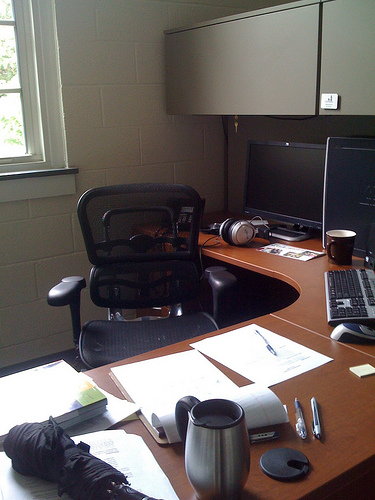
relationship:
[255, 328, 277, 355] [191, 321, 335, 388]
pen on paper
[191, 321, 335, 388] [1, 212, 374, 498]
paper on desk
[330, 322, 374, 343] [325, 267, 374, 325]
mouse next to keyboard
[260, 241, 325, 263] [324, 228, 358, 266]
brochure by mug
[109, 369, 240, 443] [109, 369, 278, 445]
clipboard on clipboard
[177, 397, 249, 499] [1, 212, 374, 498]
mug on desk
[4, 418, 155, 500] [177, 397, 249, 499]
umbrella beside mug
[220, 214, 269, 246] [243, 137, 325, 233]
headphones in front of computer monitor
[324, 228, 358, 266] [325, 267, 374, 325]
mug by keyboard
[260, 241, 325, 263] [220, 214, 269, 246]
brochure by headphones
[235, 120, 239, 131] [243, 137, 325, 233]
key dangling by computer monitor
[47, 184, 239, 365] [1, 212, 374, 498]
office chair next to desk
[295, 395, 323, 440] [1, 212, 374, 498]
pens on desk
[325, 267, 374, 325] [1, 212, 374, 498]
keyboard on desk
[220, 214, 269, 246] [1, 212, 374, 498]
headphones on desk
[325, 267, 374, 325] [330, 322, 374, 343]
keyboard and mouse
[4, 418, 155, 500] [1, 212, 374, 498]
umbrella on desk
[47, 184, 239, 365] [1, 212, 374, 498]
office chair by desk